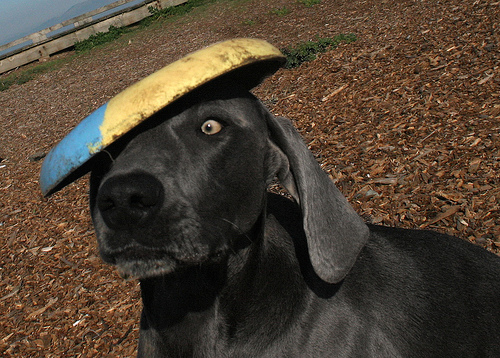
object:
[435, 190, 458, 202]
wood chip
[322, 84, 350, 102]
wood chip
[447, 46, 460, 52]
wood chip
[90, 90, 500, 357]
dog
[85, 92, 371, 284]
head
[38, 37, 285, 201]
frisbee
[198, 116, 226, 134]
eye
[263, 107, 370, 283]
ear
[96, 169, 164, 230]
nose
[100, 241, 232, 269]
mouth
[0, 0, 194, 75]
railing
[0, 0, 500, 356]
ground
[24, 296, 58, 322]
wood chip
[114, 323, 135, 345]
wood chip